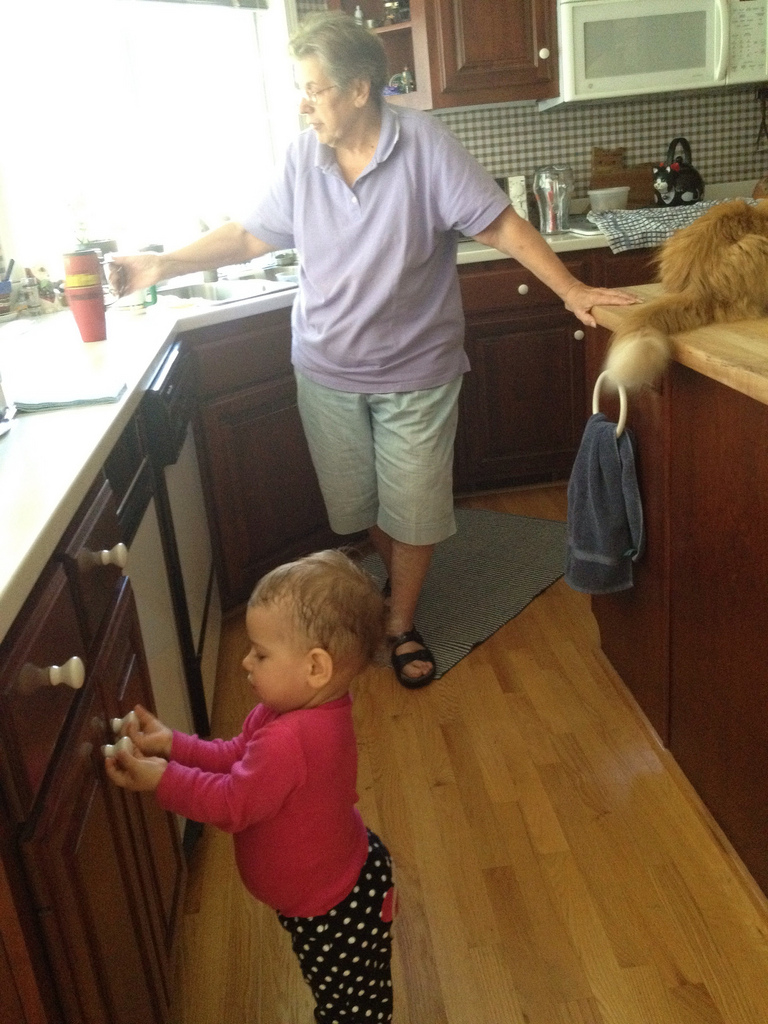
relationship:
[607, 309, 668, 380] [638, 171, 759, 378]
tail on cat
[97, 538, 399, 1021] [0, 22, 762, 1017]
child standing in kitchen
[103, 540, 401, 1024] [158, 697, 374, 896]
child wearing shirt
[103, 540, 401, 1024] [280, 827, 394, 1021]
child wearing pants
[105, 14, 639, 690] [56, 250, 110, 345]
person holding coffee mug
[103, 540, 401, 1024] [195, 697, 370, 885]
child with shirt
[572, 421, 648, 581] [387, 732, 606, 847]
rug on ground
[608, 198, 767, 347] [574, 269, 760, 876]
cat on countertop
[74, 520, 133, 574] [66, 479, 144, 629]
knob on drawer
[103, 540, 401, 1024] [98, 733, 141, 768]
child holding onto cabinet knob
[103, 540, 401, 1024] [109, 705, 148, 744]
child holding onto cabinet knob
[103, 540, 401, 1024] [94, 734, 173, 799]
child holding on with hand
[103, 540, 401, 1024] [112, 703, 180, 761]
child holding on with hand